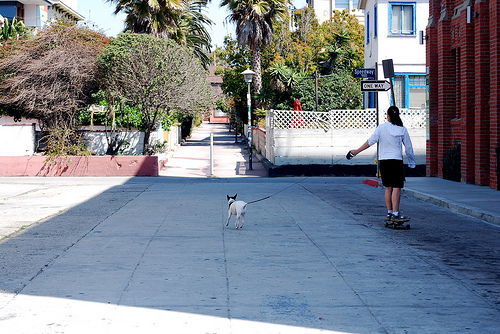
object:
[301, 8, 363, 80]
tree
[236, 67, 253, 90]
lamp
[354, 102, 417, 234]
woman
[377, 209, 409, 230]
skateboard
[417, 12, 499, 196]
wall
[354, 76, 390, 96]
sign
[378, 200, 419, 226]
skate board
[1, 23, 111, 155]
tree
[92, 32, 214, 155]
tree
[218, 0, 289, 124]
tree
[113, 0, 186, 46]
tree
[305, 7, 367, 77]
tree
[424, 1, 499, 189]
building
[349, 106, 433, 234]
girl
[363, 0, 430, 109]
building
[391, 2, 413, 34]
window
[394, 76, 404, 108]
window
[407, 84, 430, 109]
window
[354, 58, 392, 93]
street sign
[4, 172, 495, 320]
shadow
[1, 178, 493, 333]
ground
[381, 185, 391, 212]
leg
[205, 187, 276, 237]
small dog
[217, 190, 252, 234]
dog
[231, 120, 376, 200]
leash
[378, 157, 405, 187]
shorts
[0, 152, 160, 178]
wall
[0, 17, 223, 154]
plants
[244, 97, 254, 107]
poster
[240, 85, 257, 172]
post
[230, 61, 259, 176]
street lamp